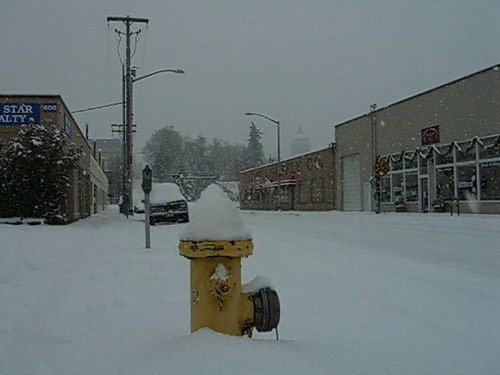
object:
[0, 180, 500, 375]
snow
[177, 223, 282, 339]
hydrant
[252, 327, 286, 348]
chain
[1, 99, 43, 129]
sign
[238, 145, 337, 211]
building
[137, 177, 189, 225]
truck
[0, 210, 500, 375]
street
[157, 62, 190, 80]
lamp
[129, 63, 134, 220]
pole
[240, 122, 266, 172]
trees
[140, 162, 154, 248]
meter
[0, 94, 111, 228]
building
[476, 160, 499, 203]
windows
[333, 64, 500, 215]
building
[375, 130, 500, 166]
garland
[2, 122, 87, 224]
tree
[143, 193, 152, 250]
pole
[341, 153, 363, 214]
door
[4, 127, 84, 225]
bush